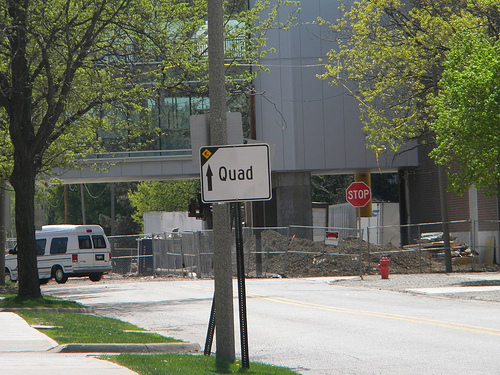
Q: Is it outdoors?
A: Yes, it is outdoors.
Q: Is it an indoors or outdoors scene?
A: It is outdoors.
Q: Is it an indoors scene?
A: No, it is outdoors.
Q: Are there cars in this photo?
A: No, there are no cars.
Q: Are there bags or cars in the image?
A: No, there are no cars or bags.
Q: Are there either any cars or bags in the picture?
A: No, there are no cars or bags.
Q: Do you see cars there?
A: No, there are no cars.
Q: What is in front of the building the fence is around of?
A: The tree is in front of the building.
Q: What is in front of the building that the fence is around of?
A: The tree is in front of the building.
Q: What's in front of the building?
A: The tree is in front of the building.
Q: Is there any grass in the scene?
A: Yes, there is grass.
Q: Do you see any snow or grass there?
A: Yes, there is grass.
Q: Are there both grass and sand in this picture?
A: No, there is grass but no sand.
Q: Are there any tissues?
A: No, there are no tissues.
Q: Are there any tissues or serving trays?
A: No, there are no tissues or serving trays.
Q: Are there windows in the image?
A: Yes, there is a window.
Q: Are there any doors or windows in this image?
A: Yes, there is a window.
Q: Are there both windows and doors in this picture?
A: No, there is a window but no doors.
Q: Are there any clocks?
A: No, there are no clocks.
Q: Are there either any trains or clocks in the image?
A: No, there are no clocks or trains.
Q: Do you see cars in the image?
A: No, there are no cars.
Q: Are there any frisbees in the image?
A: No, there are no frisbees.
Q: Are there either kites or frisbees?
A: No, there are no frisbees or kites.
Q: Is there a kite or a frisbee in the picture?
A: No, there are no frisbees or kites.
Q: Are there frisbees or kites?
A: No, there are no frisbees or kites.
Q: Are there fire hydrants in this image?
A: Yes, there is a fire hydrant.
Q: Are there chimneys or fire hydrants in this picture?
A: Yes, there is a fire hydrant.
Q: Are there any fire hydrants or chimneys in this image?
A: Yes, there is a fire hydrant.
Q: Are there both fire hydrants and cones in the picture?
A: No, there is a fire hydrant but no cones.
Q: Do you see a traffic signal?
A: No, there are no traffic lights.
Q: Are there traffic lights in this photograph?
A: No, there are no traffic lights.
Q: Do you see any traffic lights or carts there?
A: No, there are no traffic lights or carts.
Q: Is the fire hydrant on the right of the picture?
A: Yes, the fire hydrant is on the right of the image.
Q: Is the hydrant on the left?
A: No, the hydrant is on the right of the image.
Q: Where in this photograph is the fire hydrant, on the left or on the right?
A: The fire hydrant is on the right of the image.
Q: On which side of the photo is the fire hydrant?
A: The fire hydrant is on the right of the image.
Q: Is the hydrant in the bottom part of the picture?
A: Yes, the hydrant is in the bottom of the image.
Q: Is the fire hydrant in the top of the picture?
A: No, the fire hydrant is in the bottom of the image.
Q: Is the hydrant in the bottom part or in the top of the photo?
A: The hydrant is in the bottom of the image.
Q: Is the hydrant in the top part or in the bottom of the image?
A: The hydrant is in the bottom of the image.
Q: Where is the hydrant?
A: The hydrant is on the street.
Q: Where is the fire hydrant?
A: The hydrant is on the street.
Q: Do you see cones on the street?
A: No, there is a fire hydrant on the street.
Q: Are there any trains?
A: No, there are no trains.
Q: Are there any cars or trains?
A: No, there are no trains or cars.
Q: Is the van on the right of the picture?
A: No, the van is on the left of the image.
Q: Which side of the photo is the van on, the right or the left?
A: The van is on the left of the image.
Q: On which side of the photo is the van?
A: The van is on the left of the image.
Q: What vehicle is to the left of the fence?
A: The vehicle is a van.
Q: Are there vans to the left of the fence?
A: Yes, there is a van to the left of the fence.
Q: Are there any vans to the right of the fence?
A: No, the van is to the left of the fence.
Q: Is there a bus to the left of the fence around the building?
A: No, there is a van to the left of the fence.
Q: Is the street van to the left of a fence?
A: Yes, the van is to the left of a fence.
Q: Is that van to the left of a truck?
A: No, the van is to the left of a fence.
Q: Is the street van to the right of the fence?
A: No, the van is to the left of the fence.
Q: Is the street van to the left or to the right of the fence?
A: The van is to the left of the fence.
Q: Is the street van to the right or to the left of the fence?
A: The van is to the left of the fence.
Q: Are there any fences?
A: Yes, there is a fence.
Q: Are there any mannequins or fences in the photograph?
A: Yes, there is a fence.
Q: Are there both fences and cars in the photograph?
A: No, there is a fence but no cars.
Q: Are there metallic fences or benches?
A: Yes, there is a metal fence.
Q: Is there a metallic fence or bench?
A: Yes, there is a metal fence.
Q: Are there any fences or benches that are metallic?
A: Yes, the fence is metallic.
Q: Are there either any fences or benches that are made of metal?
A: Yes, the fence is made of metal.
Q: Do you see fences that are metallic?
A: Yes, there is a metal fence.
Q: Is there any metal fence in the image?
A: Yes, there is a metal fence.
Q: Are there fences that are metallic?
A: Yes, there is a fence that is metallic.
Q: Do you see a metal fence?
A: Yes, there is a fence that is made of metal.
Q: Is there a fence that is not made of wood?
A: Yes, there is a fence that is made of metal.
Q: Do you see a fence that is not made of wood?
A: Yes, there is a fence that is made of metal.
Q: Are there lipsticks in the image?
A: No, there are no lipsticks.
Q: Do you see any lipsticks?
A: No, there are no lipsticks.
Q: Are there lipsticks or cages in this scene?
A: No, there are no lipsticks or cages.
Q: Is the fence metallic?
A: Yes, the fence is metallic.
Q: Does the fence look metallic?
A: Yes, the fence is metallic.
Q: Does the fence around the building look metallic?
A: Yes, the fence is metallic.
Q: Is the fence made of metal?
A: Yes, the fence is made of metal.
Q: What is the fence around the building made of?
A: The fence is made of metal.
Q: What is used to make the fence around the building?
A: The fence is made of metal.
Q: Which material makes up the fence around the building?
A: The fence is made of metal.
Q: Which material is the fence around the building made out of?
A: The fence is made of metal.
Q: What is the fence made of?
A: The fence is made of metal.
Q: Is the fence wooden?
A: No, the fence is metallic.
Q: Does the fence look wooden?
A: No, the fence is metallic.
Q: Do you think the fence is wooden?
A: No, the fence is metallic.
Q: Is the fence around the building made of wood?
A: No, the fence is made of metal.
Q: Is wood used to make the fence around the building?
A: No, the fence is made of metal.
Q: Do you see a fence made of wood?
A: No, there is a fence but it is made of metal.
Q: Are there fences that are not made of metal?
A: No, there is a fence but it is made of metal.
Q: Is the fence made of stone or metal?
A: The fence is made of metal.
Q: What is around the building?
A: The fence is around the building.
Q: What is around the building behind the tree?
A: The fence is around the building.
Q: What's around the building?
A: The fence is around the building.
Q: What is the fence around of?
A: The fence is around the building.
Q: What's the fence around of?
A: The fence is around the building.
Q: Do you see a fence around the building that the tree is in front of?
A: Yes, there is a fence around the building.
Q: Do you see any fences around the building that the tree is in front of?
A: Yes, there is a fence around the building.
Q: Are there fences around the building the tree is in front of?
A: Yes, there is a fence around the building.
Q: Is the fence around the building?
A: Yes, the fence is around the building.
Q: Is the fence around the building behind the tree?
A: Yes, the fence is around the building.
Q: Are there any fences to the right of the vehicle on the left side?
A: Yes, there is a fence to the right of the van.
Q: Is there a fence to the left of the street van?
A: No, the fence is to the right of the van.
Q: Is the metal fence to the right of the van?
A: Yes, the fence is to the right of the van.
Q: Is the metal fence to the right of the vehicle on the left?
A: Yes, the fence is to the right of the van.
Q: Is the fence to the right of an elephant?
A: No, the fence is to the right of the van.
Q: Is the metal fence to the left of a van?
A: No, the fence is to the right of a van.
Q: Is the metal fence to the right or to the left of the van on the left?
A: The fence is to the right of the van.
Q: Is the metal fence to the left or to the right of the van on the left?
A: The fence is to the right of the van.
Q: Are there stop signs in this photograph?
A: Yes, there is a stop sign.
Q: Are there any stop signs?
A: Yes, there is a stop sign.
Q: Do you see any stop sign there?
A: Yes, there is a stop sign.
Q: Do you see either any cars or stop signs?
A: Yes, there is a stop sign.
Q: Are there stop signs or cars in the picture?
A: Yes, there is a stop sign.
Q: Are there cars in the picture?
A: No, there are no cars.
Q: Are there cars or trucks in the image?
A: No, there are no cars or trucks.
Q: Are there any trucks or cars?
A: No, there are no cars or trucks.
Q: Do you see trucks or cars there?
A: No, there are no cars or trucks.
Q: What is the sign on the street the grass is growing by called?
A: The sign is a stop sign.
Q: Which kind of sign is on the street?
A: The sign is a stop sign.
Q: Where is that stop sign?
A: The stop sign is on the street.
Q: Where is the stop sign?
A: The stop sign is on the street.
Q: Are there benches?
A: No, there are no benches.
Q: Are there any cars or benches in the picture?
A: No, there are no benches or cars.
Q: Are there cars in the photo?
A: No, there are no cars.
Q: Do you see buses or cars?
A: No, there are no cars or buses.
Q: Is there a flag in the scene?
A: No, there are no flags.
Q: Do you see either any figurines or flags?
A: No, there are no flags or figurines.